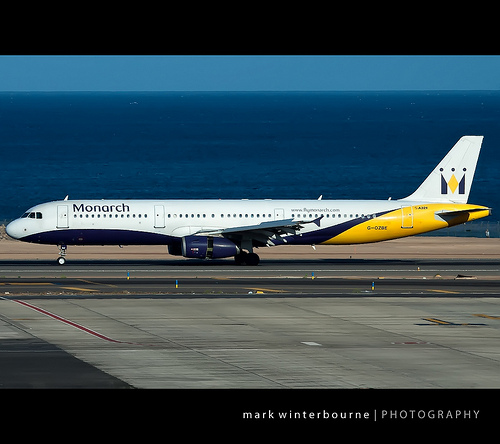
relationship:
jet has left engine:
[3, 127, 493, 270] [179, 234, 255, 264]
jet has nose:
[3, 127, 493, 270] [2, 215, 29, 242]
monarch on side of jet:
[72, 202, 132, 215] [3, 127, 493, 270]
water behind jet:
[3, 90, 499, 239] [3, 127, 493, 270]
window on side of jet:
[143, 211, 148, 220] [3, 127, 493, 270]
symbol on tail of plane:
[436, 163, 470, 199] [401, 133, 490, 202]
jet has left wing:
[3, 127, 493, 270] [191, 221, 304, 246]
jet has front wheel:
[3, 127, 493, 270] [53, 255, 71, 268]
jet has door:
[3, 127, 493, 270] [54, 202, 72, 231]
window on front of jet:
[26, 211, 40, 218] [3, 127, 493, 270]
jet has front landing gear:
[3, 127, 493, 270] [52, 239, 72, 267]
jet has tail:
[3, 127, 493, 270] [410, 128, 490, 204]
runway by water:
[3, 253, 498, 299] [3, 90, 499, 239]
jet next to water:
[3, 127, 493, 270] [3, 90, 499, 239]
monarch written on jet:
[72, 202, 132, 215] [3, 127, 493, 270]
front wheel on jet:
[53, 255, 71, 268] [3, 127, 493, 270]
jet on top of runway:
[3, 127, 493, 270] [3, 253, 498, 299]